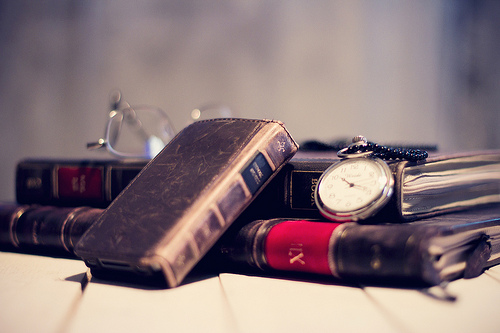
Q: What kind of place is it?
A: It is a library.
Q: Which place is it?
A: It is a library.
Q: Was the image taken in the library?
A: Yes, it was taken in the library.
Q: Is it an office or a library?
A: It is a library.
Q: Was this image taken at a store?
A: No, the picture was taken in a library.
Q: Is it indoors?
A: Yes, it is indoors.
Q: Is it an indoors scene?
A: Yes, it is indoors.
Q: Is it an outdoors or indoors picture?
A: It is indoors.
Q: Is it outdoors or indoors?
A: It is indoors.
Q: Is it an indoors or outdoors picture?
A: It is indoors.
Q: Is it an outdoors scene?
A: No, it is indoors.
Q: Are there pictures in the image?
A: No, there are no pictures.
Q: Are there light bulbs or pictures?
A: No, there are no pictures or light bulbs.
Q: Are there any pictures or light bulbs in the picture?
A: No, there are no pictures or light bulbs.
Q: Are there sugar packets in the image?
A: No, there are no sugar packets.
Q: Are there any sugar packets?
A: No, there are no sugar packets.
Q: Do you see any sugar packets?
A: No, there are no sugar packets.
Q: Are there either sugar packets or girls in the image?
A: No, there are no sugar packets or girls.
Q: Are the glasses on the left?
A: Yes, the glasses are on the left of the image.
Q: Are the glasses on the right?
A: No, the glasses are on the left of the image.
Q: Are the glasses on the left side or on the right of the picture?
A: The glasses are on the left of the image.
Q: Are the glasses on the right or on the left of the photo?
A: The glasses are on the left of the image.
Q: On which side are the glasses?
A: The glasses are on the left of the image.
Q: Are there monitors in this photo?
A: No, there are no monitors.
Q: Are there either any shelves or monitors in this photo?
A: No, there are no monitors or shelves.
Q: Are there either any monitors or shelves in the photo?
A: No, there are no monitors or shelves.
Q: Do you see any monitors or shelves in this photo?
A: No, there are no monitors or shelves.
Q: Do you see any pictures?
A: No, there are no pictures.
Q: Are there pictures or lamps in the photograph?
A: No, there are no pictures or lamps.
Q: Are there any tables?
A: Yes, there is a table.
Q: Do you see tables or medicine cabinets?
A: Yes, there is a table.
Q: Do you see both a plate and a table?
A: No, there is a table but no plates.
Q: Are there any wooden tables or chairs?
A: Yes, there is a wood table.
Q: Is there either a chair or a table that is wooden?
A: Yes, the table is wooden.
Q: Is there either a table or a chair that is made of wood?
A: Yes, the table is made of wood.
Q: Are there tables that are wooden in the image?
A: Yes, there is a wood table.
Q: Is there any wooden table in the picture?
A: Yes, there is a wood table.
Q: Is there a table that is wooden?
A: Yes, there is a table that is wooden.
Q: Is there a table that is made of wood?
A: Yes, there is a table that is made of wood.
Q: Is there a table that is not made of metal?
A: Yes, there is a table that is made of wood.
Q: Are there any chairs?
A: No, there are no chairs.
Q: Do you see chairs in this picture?
A: No, there are no chairs.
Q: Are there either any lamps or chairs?
A: No, there are no chairs or lamps.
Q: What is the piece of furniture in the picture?
A: The piece of furniture is a table.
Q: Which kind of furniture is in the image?
A: The furniture is a table.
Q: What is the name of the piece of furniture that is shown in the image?
A: The piece of furniture is a table.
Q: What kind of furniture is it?
A: The piece of furniture is a table.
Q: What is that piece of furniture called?
A: This is a table.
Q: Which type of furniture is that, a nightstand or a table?
A: This is a table.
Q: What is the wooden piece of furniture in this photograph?
A: The piece of furniture is a table.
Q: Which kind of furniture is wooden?
A: The furniture is a table.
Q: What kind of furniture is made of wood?
A: The furniture is a table.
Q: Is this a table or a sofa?
A: This is a table.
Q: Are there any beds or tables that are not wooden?
A: No, there is a table but it is wooden.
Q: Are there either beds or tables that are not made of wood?
A: No, there is a table but it is made of wood.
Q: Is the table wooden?
A: Yes, the table is wooden.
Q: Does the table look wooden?
A: Yes, the table is wooden.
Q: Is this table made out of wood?
A: Yes, the table is made of wood.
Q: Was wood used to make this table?
A: Yes, the table is made of wood.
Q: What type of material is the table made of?
A: The table is made of wood.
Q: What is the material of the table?
A: The table is made of wood.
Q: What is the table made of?
A: The table is made of wood.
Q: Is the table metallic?
A: No, the table is wooden.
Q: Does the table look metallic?
A: No, the table is wooden.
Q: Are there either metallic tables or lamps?
A: No, there is a table but it is wooden.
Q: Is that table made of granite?
A: No, the table is made of wood.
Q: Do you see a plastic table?
A: No, there is a table but it is made of wood.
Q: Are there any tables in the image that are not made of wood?
A: No, there is a table but it is made of wood.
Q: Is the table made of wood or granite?
A: The table is made of wood.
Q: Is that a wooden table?
A: Yes, that is a wooden table.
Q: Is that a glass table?
A: No, that is a wooden table.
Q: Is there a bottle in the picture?
A: No, there are no bottles.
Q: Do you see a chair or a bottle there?
A: No, there are no bottles or chairs.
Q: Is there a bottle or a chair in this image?
A: No, there are no bottles or chairs.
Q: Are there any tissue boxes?
A: No, there are no tissue boxes.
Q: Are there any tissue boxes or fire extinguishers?
A: No, there are no tissue boxes or fire extinguishers.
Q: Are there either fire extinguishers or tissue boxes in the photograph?
A: No, there are no tissue boxes or fire extinguishers.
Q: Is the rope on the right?
A: Yes, the rope is on the right of the image.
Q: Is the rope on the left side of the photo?
A: No, the rope is on the right of the image.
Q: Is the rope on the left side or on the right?
A: The rope is on the right of the image.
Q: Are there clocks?
A: Yes, there is a clock.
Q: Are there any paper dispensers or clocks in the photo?
A: Yes, there is a clock.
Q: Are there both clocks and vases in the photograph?
A: No, there is a clock but no vases.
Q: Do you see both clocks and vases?
A: No, there is a clock but no vases.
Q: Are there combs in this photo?
A: No, there are no combs.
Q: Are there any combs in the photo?
A: No, there are no combs.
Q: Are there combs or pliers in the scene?
A: No, there are no combs or pliers.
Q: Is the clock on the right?
A: Yes, the clock is on the right of the image.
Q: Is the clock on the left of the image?
A: No, the clock is on the right of the image.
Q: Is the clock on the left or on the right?
A: The clock is on the right of the image.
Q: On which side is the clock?
A: The clock is on the right of the image.